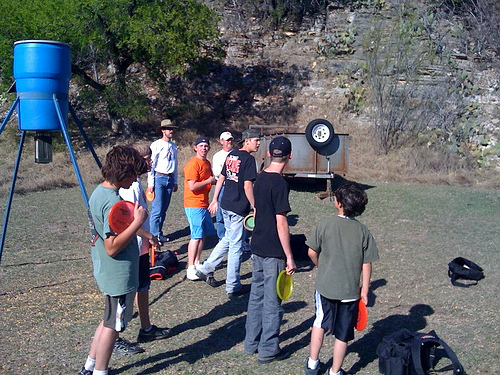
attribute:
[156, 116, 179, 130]
hat — cowboy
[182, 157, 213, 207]
shirt — orange, bright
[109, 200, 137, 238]
frisbee — red, yellow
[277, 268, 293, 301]
frisbee — yellow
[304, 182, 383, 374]
boy — young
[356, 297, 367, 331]
frisbee — orange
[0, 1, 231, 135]
tree — green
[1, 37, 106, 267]
object — blue, large, tank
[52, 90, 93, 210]
leg — blue, metal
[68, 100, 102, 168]
leg — blue, metal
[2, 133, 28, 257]
leg — blue, metal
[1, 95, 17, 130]
leg — blue, metal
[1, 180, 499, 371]
grass — green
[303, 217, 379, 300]
tee shirt — grey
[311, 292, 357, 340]
shorts — dark, black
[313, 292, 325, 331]
stripe — white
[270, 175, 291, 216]
sleeve — short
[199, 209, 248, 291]
jeans — blue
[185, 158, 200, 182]
sleeve — short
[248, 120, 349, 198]
trailer — rusty, metal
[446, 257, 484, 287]
bag — black